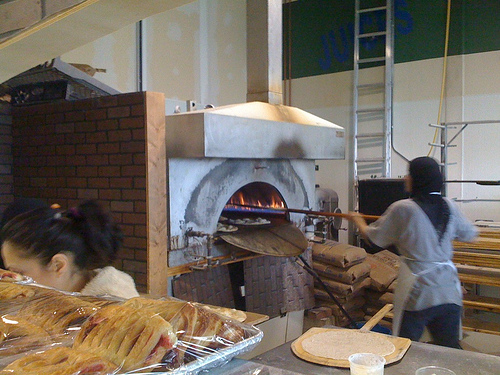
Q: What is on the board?
A: Pizza dough.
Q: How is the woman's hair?
A: The woman's hair is up.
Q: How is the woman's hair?
A: The woman has a pony tail.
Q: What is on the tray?
A: Pastries are on the tray.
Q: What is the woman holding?
A: The woman is a long spatula.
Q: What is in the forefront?
A: Freshly made berry filled strudels.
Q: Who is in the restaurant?
A: A cook.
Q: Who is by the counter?
A: An assistant.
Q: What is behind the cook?
A: Large bags of flour.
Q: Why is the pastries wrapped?
A: To stay fresh.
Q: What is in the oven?
A: A large pizza pie.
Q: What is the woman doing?
A: Putting pizza in the oven.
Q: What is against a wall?
A: A ladder.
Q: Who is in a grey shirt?
A: A woman.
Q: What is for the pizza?
A: A stone oven.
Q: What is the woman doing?
A: Placing pizza in oven.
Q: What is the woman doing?
A: Placing pizza in stone oven.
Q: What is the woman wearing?
A: An apron.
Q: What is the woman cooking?
A: Pizza.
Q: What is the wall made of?
A: Brick.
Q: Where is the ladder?
A: Next to the wall.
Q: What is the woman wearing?
A: An apron.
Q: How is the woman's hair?
A: In a pony tail.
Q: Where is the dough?
A: On the pizza.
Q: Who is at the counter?
A: A woman.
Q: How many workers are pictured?
A: Two.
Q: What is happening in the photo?
A: Pizza crusts are being baked.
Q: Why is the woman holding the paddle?
A: So she can slide the dough into the oven.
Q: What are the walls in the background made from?
A: Unfinished drywall.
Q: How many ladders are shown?
A: One.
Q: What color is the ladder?
A: Silver.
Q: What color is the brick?
A: Orange.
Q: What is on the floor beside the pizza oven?
A: Bags.